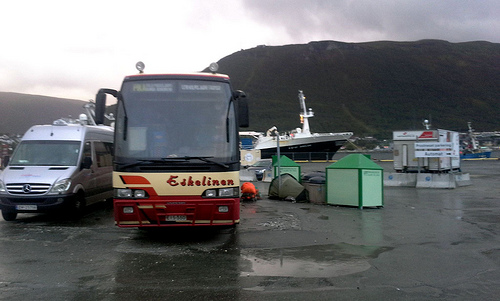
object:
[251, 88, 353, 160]
boat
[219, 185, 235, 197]
headlight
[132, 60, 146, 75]
light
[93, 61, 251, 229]
bus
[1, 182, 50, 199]
grille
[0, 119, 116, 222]
van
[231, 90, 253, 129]
mirror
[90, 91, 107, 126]
mirror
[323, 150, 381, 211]
tent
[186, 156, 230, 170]
wiper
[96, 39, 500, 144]
mountain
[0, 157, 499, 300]
parking lot